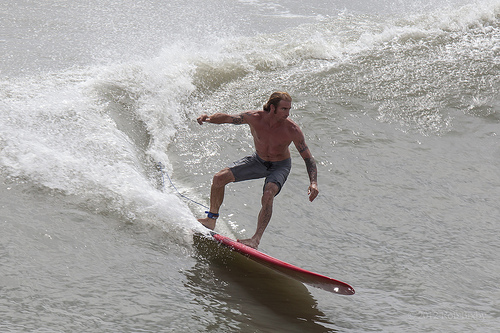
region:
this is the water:
[17, 235, 105, 305]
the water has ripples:
[21, 225, 109, 301]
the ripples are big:
[43, 227, 110, 291]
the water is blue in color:
[62, 248, 143, 300]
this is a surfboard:
[207, 223, 358, 306]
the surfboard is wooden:
[242, 244, 255, 257]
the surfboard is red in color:
[246, 248, 256, 263]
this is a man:
[193, 79, 327, 247]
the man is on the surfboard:
[184, 87, 326, 245]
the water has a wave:
[66, 81, 139, 156]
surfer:
[178, 92, 322, 269]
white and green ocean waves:
[35, 113, 83, 164]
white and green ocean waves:
[397, 152, 434, 196]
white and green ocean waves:
[398, 215, 432, 259]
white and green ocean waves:
[308, 59, 375, 119]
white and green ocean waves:
[341, 25, 426, 110]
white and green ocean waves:
[105, 103, 149, 131]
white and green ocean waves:
[65, 89, 125, 156]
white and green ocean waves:
[84, 221, 144, 263]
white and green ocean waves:
[78, 25, 146, 103]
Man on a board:
[182, 216, 357, 302]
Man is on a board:
[179, 212, 361, 300]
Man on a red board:
[175, 216, 359, 306]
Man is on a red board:
[183, 207, 356, 296]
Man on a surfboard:
[185, 208, 360, 298]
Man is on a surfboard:
[180, 215, 355, 300]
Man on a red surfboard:
[187, 210, 362, 301]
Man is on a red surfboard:
[190, 217, 361, 299]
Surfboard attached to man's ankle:
[191, 205, 361, 305]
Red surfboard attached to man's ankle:
[170, 207, 360, 305]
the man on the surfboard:
[196, 90, 318, 248]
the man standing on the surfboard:
[197, 90, 319, 249]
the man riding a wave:
[182, 90, 354, 293]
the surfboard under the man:
[191, 219, 354, 295]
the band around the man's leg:
[205, 208, 219, 221]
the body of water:
[1, 2, 497, 330]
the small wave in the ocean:
[0, 0, 499, 272]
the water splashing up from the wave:
[0, 0, 499, 267]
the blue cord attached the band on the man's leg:
[156, 160, 219, 219]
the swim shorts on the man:
[228, 150, 291, 195]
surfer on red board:
[181, 75, 346, 286]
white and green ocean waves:
[40, 41, 77, 101]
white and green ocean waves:
[47, 276, 91, 308]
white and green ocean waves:
[40, 121, 98, 189]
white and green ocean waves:
[368, 42, 445, 144]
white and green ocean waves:
[15, 72, 70, 130]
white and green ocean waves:
[58, 68, 133, 138]